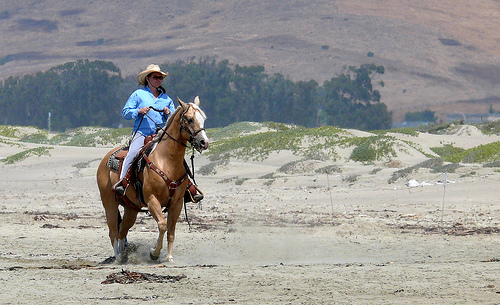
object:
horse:
[97, 95, 210, 264]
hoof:
[150, 251, 161, 260]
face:
[182, 109, 208, 145]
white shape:
[195, 111, 208, 140]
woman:
[115, 64, 175, 194]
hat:
[136, 64, 168, 86]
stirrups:
[111, 134, 205, 203]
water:
[390, 124, 406, 129]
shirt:
[121, 85, 176, 137]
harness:
[106, 134, 205, 217]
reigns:
[132, 103, 206, 186]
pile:
[217, 158, 362, 188]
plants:
[1, 121, 499, 168]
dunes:
[0, 120, 499, 195]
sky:
[2, 1, 487, 68]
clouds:
[0, 0, 498, 131]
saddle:
[144, 134, 157, 145]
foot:
[116, 179, 125, 195]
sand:
[0, 217, 499, 305]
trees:
[0, 52, 500, 131]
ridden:
[97, 64, 210, 265]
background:
[0, 0, 498, 129]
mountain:
[0, 0, 499, 122]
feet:
[150, 247, 163, 261]